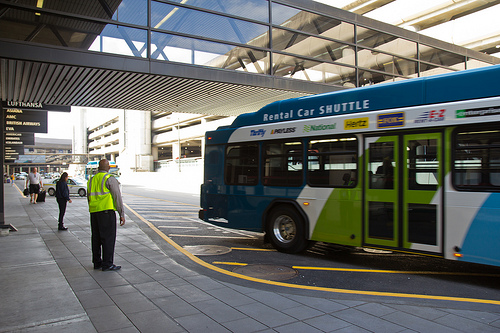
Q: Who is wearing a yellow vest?
A: The man standing by the bus.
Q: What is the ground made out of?
A: Concrete.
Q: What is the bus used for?
A: Transporting people.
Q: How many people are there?
A: Three.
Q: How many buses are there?
A: One.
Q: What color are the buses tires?
A: Black.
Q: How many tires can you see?
A: One.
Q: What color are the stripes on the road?
A: Yellow.